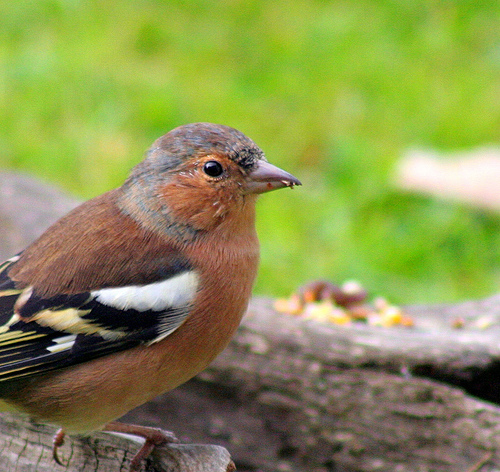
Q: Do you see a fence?
A: No, there are no fences.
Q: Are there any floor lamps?
A: No, there are no floor lamps.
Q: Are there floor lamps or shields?
A: No, there are no floor lamps or shields.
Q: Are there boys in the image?
A: No, there are no boys.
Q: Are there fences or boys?
A: No, there are no boys or fences.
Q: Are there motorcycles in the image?
A: No, there are no motorcycles.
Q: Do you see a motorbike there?
A: No, there are no motorcycles.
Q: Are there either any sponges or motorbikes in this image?
A: No, there are no motorbikes or sponges.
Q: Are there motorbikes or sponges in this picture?
A: No, there are no motorbikes or sponges.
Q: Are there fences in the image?
A: No, there are no fences.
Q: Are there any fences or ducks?
A: No, there are no fences or ducks.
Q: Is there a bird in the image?
A: Yes, there is a bird.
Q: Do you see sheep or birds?
A: Yes, there is a bird.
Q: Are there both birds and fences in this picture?
A: No, there is a bird but no fences.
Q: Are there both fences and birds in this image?
A: No, there is a bird but no fences.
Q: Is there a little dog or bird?
A: Yes, there is a little bird.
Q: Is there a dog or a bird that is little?
A: Yes, the bird is little.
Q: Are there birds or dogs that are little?
A: Yes, the bird is little.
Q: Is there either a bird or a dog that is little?
A: Yes, the bird is little.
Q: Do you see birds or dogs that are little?
A: Yes, the bird is little.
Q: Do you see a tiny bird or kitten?
A: Yes, there is a tiny bird.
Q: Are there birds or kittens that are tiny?
A: Yes, the bird is tiny.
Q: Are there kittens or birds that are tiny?
A: Yes, the bird is tiny.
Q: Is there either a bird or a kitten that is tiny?
A: Yes, the bird is tiny.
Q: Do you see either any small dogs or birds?
A: Yes, there is a small bird.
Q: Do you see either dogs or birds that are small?
A: Yes, the bird is small.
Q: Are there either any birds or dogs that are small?
A: Yes, the bird is small.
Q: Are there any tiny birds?
A: Yes, there is a tiny bird.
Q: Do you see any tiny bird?
A: Yes, there is a tiny bird.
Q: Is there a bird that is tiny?
A: Yes, there is a bird that is tiny.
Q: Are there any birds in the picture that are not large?
A: Yes, there is a tiny bird.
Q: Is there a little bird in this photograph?
A: Yes, there is a little bird.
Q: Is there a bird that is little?
A: Yes, there is a bird that is little.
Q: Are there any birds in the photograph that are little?
A: Yes, there is a bird that is little.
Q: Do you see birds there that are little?
A: Yes, there is a bird that is little.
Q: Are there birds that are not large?
A: Yes, there is a little bird.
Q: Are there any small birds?
A: Yes, there is a small bird.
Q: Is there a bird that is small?
A: Yes, there is a bird that is small.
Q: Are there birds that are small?
A: Yes, there is a bird that is small.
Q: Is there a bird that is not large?
A: Yes, there is a small bird.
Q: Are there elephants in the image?
A: No, there are no elephants.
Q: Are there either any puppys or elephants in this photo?
A: No, there are no elephants or puppys.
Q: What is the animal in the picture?
A: The animal is a bird.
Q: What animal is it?
A: The animal is a bird.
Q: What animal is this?
A: This is a bird.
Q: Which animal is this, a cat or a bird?
A: This is a bird.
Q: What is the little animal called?
A: The animal is a bird.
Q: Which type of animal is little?
A: The animal is a bird.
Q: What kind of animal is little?
A: The animal is a bird.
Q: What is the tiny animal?
A: The animal is a bird.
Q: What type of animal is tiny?
A: The animal is a bird.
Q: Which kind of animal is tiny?
A: The animal is a bird.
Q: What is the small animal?
A: The animal is a bird.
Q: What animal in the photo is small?
A: The animal is a bird.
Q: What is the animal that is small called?
A: The animal is a bird.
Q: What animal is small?
A: The animal is a bird.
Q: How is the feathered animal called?
A: The animal is a bird.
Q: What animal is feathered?
A: The animal is a bird.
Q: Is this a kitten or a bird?
A: This is a bird.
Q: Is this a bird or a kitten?
A: This is a bird.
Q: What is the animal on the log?
A: The animal is a bird.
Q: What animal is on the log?
A: The animal is a bird.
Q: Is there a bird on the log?
A: Yes, there is a bird on the log.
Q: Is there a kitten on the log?
A: No, there is a bird on the log.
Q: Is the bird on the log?
A: Yes, the bird is on the log.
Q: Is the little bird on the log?
A: Yes, the bird is on the log.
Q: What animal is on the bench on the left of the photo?
A: The bird is on the bench.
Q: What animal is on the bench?
A: The bird is on the bench.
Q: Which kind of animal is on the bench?
A: The animal is a bird.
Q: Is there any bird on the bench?
A: Yes, there is a bird on the bench.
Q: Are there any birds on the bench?
A: Yes, there is a bird on the bench.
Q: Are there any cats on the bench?
A: No, there is a bird on the bench.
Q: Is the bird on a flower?
A: No, the bird is on the bench.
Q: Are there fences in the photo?
A: No, there are no fences.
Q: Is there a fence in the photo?
A: No, there are no fences.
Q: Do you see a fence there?
A: No, there are no fences.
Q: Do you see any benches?
A: Yes, there is a bench.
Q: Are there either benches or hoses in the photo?
A: Yes, there is a bench.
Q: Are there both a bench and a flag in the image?
A: No, there is a bench but no flags.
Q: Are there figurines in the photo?
A: No, there are no figurines.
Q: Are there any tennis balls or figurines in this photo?
A: No, there are no figurines or tennis balls.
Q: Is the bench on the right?
A: No, the bench is on the left of the image.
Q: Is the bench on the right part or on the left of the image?
A: The bench is on the left of the image.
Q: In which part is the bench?
A: The bench is on the left of the image.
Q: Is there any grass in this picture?
A: Yes, there is grass.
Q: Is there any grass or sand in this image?
A: Yes, there is grass.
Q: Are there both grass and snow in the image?
A: No, there is grass but no snow.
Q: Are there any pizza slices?
A: No, there are no pizza slices.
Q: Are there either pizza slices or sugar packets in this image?
A: No, there are no pizza slices or sugar packets.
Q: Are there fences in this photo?
A: No, there are no fences.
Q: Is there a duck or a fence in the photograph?
A: No, there are no fences or ducks.